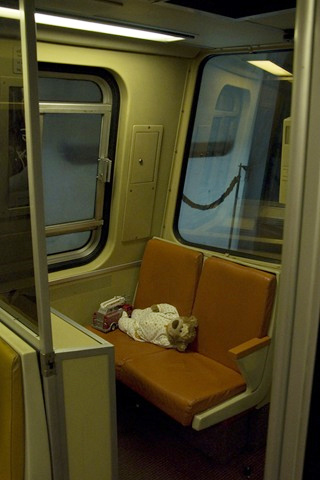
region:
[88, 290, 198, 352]
a red fire truck and a teddy bear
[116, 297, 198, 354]
a teddy bear wearing a white outfit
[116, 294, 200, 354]
a teddy bear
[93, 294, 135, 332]
a red toy fire truck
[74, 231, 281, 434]
a couple of brown seats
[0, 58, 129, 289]
a closed train window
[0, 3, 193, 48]
a long light on the roof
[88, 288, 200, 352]
a pair of toys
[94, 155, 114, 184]
a handle on the window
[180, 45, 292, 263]
reflection in the window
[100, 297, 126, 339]
red fire truck toy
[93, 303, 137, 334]
red fire truck toy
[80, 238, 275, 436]
a firetruck and a teddy bear on a bus seat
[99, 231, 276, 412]
orange seat covers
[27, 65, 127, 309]
a window on a bus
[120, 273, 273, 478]
the carper under a bus seat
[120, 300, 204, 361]
a brown teddy bear wearing a garment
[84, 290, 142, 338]
a small red firetruck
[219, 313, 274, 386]
an arm rest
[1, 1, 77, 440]
a tall divider between seats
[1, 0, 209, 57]
rectangular light on the ceiling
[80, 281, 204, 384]
two children's toys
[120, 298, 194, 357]
teddy bear laying on seat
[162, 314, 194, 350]
face of teddy bear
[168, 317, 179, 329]
nose of teddy bear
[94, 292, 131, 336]
fire truck on seat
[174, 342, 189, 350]
ear of teddy bear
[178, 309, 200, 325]
ear of teddy bear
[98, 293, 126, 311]
ladder on top of fire truck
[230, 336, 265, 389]
arm rest on seat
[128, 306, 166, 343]
pajamas on teddy bear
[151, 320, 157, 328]
button on pajamas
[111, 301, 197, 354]
this is a bear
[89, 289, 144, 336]
this is a truck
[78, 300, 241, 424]
this is a seat cushion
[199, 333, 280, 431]
this is a chair arm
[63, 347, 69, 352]
this is the color gray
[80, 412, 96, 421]
this is the color yellow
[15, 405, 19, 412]
this is the color brown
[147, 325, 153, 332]
this is the color white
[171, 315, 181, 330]
this is a nose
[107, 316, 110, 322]
this is the color red